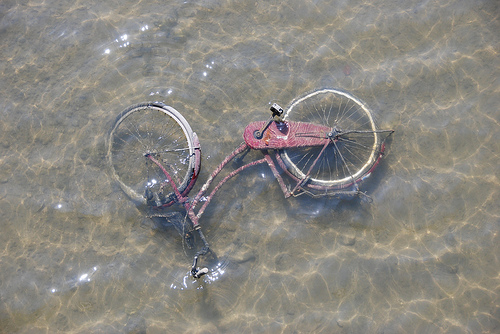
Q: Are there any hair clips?
A: No, there are no hair clips.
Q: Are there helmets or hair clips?
A: No, there are no hair clips or helmets.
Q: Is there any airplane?
A: No, there are no airplanes.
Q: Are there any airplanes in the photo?
A: No, there are no airplanes.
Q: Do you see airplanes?
A: No, there are no airplanes.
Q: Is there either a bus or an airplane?
A: No, there are no airplanes or buses.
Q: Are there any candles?
A: No, there are no candles.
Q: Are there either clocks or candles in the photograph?
A: No, there are no candles or clocks.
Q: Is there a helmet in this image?
A: No, there are no helmets.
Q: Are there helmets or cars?
A: No, there are no helmets or cars.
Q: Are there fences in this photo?
A: No, there are no fences.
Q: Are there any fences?
A: No, there are no fences.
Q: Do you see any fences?
A: No, there are no fences.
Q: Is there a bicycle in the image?
A: Yes, there is a bicycle.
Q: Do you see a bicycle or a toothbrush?
A: Yes, there is a bicycle.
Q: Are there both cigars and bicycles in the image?
A: No, there is a bicycle but no cigars.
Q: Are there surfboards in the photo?
A: No, there are no surfboards.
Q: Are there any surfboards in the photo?
A: No, there are no surfboards.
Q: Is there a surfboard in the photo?
A: No, there are no surfboards.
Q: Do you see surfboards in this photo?
A: No, there are no surfboards.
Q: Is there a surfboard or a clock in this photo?
A: No, there are no surfboards or clocks.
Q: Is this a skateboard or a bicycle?
A: This is a bicycle.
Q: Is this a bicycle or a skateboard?
A: This is a bicycle.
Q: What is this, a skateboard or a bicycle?
A: This is a bicycle.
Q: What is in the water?
A: The bicycle is in the water.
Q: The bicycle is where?
A: The bicycle is in the water.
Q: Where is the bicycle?
A: The bicycle is in the water.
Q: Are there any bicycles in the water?
A: Yes, there is a bicycle in the water.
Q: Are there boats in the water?
A: No, there is a bicycle in the water.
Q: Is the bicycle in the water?
A: Yes, the bicycle is in the water.